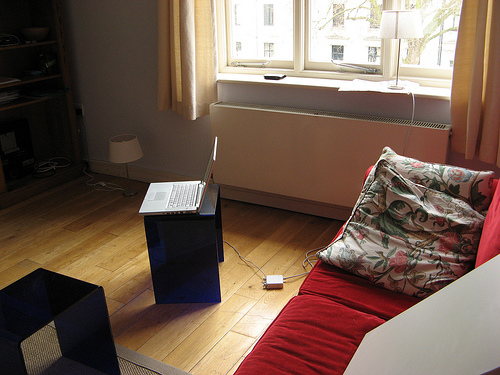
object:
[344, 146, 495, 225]
pillow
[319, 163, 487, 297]
pillow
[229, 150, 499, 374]
couch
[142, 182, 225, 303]
wood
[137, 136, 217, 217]
laptop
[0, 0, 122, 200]
corner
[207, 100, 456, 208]
radiator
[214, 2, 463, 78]
window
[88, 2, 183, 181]
wall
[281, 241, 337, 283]
cord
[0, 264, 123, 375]
stool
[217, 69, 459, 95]
windowsill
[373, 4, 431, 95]
lamp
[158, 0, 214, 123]
curtain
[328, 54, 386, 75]
silver lever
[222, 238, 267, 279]
cord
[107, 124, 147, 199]
lamp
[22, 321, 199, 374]
rug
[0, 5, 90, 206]
entertainment center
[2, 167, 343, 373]
floor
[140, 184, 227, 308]
table